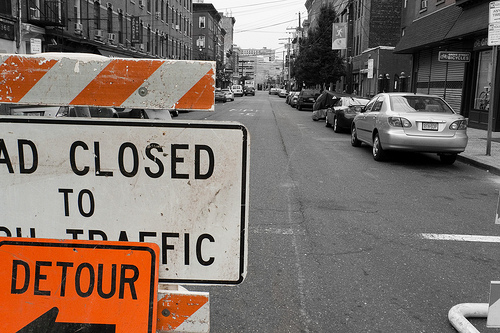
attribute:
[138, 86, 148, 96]
bolt — silver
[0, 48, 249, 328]
traffic barrier — orange, white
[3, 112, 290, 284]
sign — black, white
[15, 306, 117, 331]
arrow — black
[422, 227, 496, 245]
line — white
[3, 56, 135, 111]
specks — white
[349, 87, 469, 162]
car — silver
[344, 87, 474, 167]
car — silver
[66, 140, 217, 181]
word — closed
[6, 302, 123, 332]
arrow — black, detour sign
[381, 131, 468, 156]
bumper — rear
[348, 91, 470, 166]
car — silver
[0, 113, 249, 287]
sign — white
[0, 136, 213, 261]
lettering — black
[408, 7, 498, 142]
facade — building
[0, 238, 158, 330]
sign — orange, black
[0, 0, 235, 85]
buildings — apartment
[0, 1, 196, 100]
building — city